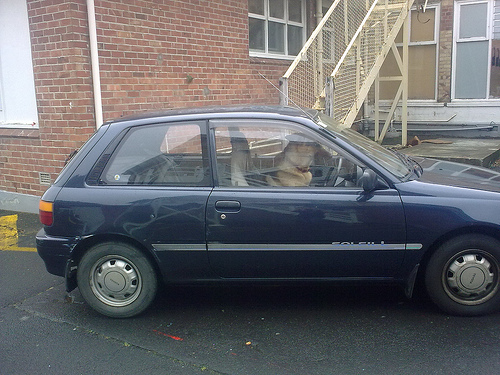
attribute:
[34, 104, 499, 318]
car — blue, small, older, parked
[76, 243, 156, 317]
back tire — worn, black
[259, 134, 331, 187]
dog — big, brown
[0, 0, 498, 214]
building — red, brick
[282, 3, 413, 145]
stairway — white, outdoor, metal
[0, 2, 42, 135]
window — white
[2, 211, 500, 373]
street — black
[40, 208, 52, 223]
light — red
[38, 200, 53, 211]
light — orange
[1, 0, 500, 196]
exterior — brick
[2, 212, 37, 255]
paint — yellow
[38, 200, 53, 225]
tail light — orange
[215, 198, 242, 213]
handle — blue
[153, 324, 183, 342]
streak — red